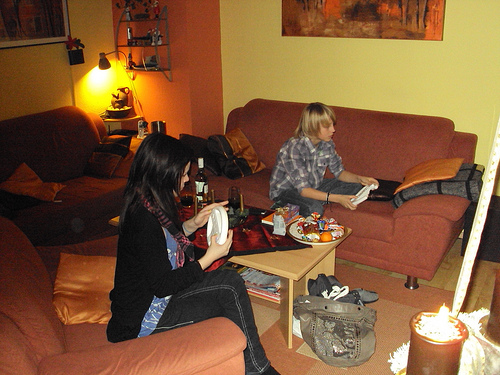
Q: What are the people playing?
A: Wii.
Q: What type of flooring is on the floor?
A: Hardwood.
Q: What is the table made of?
A: Wood.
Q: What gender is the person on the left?
A: Female.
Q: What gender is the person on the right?
A: Male.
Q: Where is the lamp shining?
A: On the wall.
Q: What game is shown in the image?
A: Video game.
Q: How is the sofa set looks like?
A: Good.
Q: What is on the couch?
A: Pillows.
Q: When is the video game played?
A: Free time.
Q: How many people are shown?
A: Two.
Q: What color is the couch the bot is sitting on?
A: Red.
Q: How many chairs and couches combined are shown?
A: Three.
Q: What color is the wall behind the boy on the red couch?
A: Yellow.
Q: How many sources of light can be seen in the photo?
A: Two.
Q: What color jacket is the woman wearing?
A: Black.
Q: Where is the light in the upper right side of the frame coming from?
A: Lamp.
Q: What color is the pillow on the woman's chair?
A: Orange.